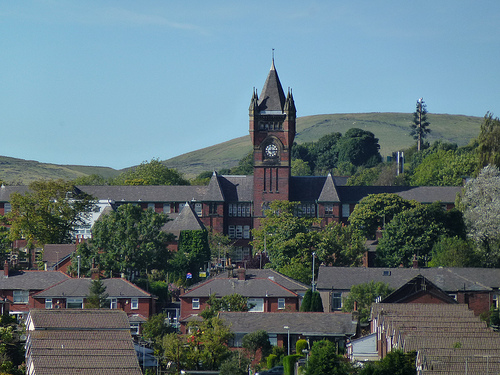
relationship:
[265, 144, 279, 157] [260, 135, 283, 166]
face of clock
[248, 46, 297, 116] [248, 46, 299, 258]
roof of clock tower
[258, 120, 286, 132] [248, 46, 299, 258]
windows on clock tower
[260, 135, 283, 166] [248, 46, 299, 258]
clock in clock tower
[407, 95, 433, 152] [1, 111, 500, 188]
tree on hills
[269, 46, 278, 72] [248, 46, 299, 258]
spire on clock tower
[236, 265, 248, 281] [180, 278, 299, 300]
chimney on roof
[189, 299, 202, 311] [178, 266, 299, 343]
window in house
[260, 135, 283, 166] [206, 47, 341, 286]
clock outside building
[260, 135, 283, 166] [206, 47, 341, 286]
clock at top of a building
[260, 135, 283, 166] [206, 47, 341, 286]
clock on building